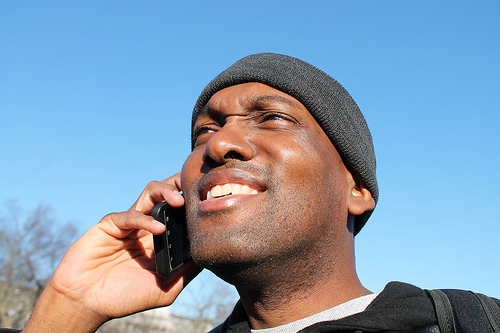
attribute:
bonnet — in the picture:
[188, 21, 408, 206]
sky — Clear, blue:
[2, 0, 496, 313]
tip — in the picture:
[347, 204, 366, 214]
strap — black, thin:
[423, 283, 455, 330]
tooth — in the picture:
[223, 182, 231, 193]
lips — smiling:
[196, 167, 268, 212]